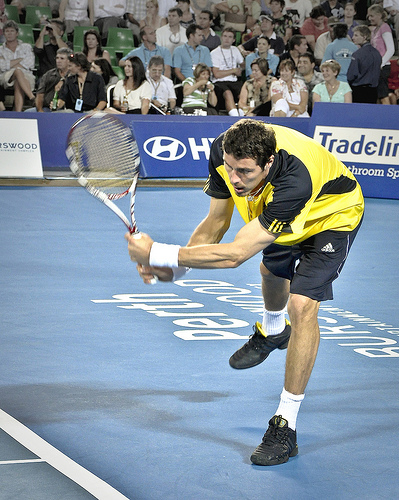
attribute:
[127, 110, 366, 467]
man — playing, swinging, leaning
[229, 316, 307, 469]
shoes — black, dark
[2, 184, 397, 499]
court — blue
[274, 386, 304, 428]
sock — white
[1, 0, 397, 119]
spectators — looking, watching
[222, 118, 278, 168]
hair — dark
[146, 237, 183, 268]
wrist band — white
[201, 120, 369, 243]
shirt — black, yellow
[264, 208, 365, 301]
shorts — black, pair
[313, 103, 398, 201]
advertisement — bright, large, promotional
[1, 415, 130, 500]
line — bright, white, long, light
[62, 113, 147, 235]
racket — tennis